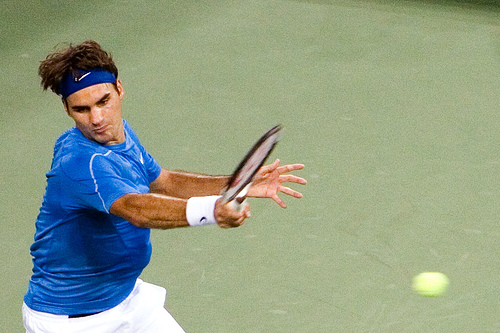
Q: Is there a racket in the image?
A: Yes, there is a racket.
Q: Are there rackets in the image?
A: Yes, there is a racket.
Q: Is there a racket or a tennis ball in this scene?
A: Yes, there is a racket.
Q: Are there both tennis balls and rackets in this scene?
A: Yes, there are both a racket and a tennis ball.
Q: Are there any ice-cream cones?
A: No, there are no ice-cream cones.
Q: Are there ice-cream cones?
A: No, there are no ice-cream cones.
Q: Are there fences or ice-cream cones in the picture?
A: No, there are no ice-cream cones or fences.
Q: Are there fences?
A: No, there are no fences.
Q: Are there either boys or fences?
A: No, there are no fences or boys.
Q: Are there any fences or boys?
A: No, there are no fences or boys.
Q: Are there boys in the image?
A: No, there are no boys.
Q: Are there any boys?
A: No, there are no boys.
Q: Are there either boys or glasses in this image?
A: No, there are no boys or glasses.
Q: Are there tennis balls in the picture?
A: Yes, there is a tennis ball.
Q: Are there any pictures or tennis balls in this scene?
A: Yes, there is a tennis ball.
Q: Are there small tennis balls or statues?
A: Yes, there is a small tennis ball.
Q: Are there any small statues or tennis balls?
A: Yes, there is a small tennis ball.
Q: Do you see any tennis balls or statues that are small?
A: Yes, the tennis ball is small.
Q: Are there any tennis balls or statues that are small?
A: Yes, the tennis ball is small.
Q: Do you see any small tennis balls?
A: Yes, there is a small tennis ball.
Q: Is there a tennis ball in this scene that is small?
A: Yes, there is a tennis ball that is small.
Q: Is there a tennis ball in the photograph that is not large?
A: Yes, there is a small tennis ball.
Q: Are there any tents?
A: No, there are no tents.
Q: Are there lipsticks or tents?
A: No, there are no tents or lipsticks.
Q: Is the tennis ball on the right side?
A: Yes, the tennis ball is on the right of the image.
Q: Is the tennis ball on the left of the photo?
A: No, the tennis ball is on the right of the image.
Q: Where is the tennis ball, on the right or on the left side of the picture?
A: The tennis ball is on the right of the image.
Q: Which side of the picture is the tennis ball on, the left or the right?
A: The tennis ball is on the right of the image.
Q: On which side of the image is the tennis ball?
A: The tennis ball is on the right of the image.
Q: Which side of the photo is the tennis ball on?
A: The tennis ball is on the right of the image.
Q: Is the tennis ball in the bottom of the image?
A: Yes, the tennis ball is in the bottom of the image.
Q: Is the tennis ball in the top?
A: No, the tennis ball is in the bottom of the image.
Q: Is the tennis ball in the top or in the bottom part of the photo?
A: The tennis ball is in the bottom of the image.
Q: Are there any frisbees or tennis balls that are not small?
A: No, there is a tennis ball but it is small.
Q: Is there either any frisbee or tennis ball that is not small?
A: No, there is a tennis ball but it is small.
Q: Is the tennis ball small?
A: Yes, the tennis ball is small.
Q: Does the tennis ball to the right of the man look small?
A: Yes, the tennis ball is small.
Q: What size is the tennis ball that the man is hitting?
A: The tennis ball is small.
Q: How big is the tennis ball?
A: The tennis ball is small.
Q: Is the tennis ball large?
A: No, the tennis ball is small.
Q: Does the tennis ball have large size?
A: No, the tennis ball is small.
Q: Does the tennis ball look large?
A: No, the tennis ball is small.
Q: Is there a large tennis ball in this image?
A: No, there is a tennis ball but it is small.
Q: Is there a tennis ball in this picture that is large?
A: No, there is a tennis ball but it is small.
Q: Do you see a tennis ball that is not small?
A: No, there is a tennis ball but it is small.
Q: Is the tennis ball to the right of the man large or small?
A: The tennis ball is small.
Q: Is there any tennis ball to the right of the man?
A: Yes, there is a tennis ball to the right of the man.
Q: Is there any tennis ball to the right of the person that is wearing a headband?
A: Yes, there is a tennis ball to the right of the man.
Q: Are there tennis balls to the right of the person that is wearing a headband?
A: Yes, there is a tennis ball to the right of the man.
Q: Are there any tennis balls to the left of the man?
A: No, the tennis ball is to the right of the man.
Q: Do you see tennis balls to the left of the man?
A: No, the tennis ball is to the right of the man.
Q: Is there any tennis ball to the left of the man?
A: No, the tennis ball is to the right of the man.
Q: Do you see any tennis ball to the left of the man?
A: No, the tennis ball is to the right of the man.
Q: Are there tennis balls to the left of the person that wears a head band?
A: No, the tennis ball is to the right of the man.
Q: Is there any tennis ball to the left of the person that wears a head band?
A: No, the tennis ball is to the right of the man.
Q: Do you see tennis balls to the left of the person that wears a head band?
A: No, the tennis ball is to the right of the man.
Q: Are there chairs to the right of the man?
A: No, there is a tennis ball to the right of the man.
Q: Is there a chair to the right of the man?
A: No, there is a tennis ball to the right of the man.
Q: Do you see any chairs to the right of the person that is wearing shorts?
A: No, there is a tennis ball to the right of the man.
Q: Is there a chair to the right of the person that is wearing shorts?
A: No, there is a tennis ball to the right of the man.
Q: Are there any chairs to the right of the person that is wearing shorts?
A: No, there is a tennis ball to the right of the man.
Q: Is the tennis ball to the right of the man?
A: Yes, the tennis ball is to the right of the man.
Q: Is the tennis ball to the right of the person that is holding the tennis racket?
A: Yes, the tennis ball is to the right of the man.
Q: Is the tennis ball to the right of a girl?
A: No, the tennis ball is to the right of the man.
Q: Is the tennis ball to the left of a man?
A: No, the tennis ball is to the right of a man.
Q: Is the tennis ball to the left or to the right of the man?
A: The tennis ball is to the right of the man.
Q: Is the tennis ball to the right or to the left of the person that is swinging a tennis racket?
A: The tennis ball is to the right of the man.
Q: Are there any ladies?
A: No, there are no ladies.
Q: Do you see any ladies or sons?
A: No, there are no ladies or sons.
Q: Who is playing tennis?
A: The man is playing tennis.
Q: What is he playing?
A: The man is playing tennis.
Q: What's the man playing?
A: The man is playing tennis.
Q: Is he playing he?
A: Yes, the man is playing tennis.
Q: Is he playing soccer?
A: No, the man is playing tennis.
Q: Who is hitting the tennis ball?
A: The man is hitting the tennis ball.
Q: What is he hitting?
A: The man is hitting the tennis ball.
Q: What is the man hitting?
A: The man is hitting the tennis ball.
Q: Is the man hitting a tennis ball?
A: Yes, the man is hitting a tennis ball.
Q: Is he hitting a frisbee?
A: No, the man is hitting a tennis ball.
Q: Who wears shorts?
A: The man wears shorts.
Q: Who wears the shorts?
A: The man wears shorts.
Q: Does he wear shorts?
A: Yes, the man wears shorts.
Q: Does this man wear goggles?
A: No, the man wears shorts.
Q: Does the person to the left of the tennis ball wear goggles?
A: No, the man wears shorts.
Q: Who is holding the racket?
A: The man is holding the racket.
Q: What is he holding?
A: The man is holding the racket.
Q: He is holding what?
A: The man is holding the racket.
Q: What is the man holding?
A: The man is holding the racket.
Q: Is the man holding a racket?
A: Yes, the man is holding a racket.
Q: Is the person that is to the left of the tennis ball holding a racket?
A: Yes, the man is holding a racket.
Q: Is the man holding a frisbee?
A: No, the man is holding a racket.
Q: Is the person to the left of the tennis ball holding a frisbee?
A: No, the man is holding a racket.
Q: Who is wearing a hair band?
A: The man is wearing a hair band.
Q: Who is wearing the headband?
A: The man is wearing a hair band.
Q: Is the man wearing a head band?
A: Yes, the man is wearing a head band.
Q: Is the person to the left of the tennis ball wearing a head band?
A: Yes, the man is wearing a head band.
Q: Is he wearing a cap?
A: No, the man is wearing a head band.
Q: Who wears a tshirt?
A: The man wears a tshirt.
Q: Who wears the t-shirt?
A: The man wears a tshirt.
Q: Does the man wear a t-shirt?
A: Yes, the man wears a t-shirt.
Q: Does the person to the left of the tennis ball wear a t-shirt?
A: Yes, the man wears a t-shirt.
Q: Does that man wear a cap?
A: No, the man wears a t-shirt.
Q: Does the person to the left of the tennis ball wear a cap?
A: No, the man wears a t-shirt.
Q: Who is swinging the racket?
A: The man is swinging the racket.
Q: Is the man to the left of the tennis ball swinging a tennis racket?
A: Yes, the man is swinging a tennis racket.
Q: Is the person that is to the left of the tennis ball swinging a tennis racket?
A: Yes, the man is swinging a tennis racket.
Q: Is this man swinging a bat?
A: No, the man is swinging a tennis racket.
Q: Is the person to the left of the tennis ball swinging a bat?
A: No, the man is swinging a tennis racket.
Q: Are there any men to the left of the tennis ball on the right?
A: Yes, there is a man to the left of the tennis ball.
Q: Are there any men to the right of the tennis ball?
A: No, the man is to the left of the tennis ball.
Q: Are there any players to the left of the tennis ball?
A: No, there is a man to the left of the tennis ball.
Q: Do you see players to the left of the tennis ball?
A: No, there is a man to the left of the tennis ball.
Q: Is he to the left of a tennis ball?
A: Yes, the man is to the left of a tennis ball.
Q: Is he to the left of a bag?
A: No, the man is to the left of a tennis ball.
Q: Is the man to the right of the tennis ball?
A: No, the man is to the left of the tennis ball.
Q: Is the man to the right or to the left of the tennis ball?
A: The man is to the left of the tennis ball.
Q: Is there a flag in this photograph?
A: No, there are no flags.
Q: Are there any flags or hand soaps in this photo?
A: No, there are no flags or hand soaps.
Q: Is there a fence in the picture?
A: No, there are no fences.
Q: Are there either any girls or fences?
A: No, there are no fences or girls.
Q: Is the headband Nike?
A: Yes, the headband is nike.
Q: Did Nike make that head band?
A: Yes, the head band was made by nike.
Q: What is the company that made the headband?
A: The company that made the headband is nike.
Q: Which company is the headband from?
A: The headband is from nike.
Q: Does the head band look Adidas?
A: No, the head band is nike.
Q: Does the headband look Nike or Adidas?
A: The headband is nike.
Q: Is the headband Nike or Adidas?
A: The headband is nike.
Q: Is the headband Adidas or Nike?
A: The headband is nike.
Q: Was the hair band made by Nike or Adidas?
A: The hair band was made nike.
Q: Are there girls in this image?
A: No, there are no girls.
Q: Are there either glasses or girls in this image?
A: No, there are no girls or glasses.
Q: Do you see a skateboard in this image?
A: No, there are no skateboards.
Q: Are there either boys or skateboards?
A: No, there are no skateboards or boys.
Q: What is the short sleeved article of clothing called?
A: The clothing item is a t-shirt.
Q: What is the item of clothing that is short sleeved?
A: The clothing item is a t-shirt.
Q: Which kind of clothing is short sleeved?
A: The clothing is a t-shirt.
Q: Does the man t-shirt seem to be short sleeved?
A: Yes, the tee shirt is short sleeved.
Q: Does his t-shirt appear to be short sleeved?
A: Yes, the tee shirt is short sleeved.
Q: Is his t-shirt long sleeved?
A: No, the t-shirt is short sleeved.